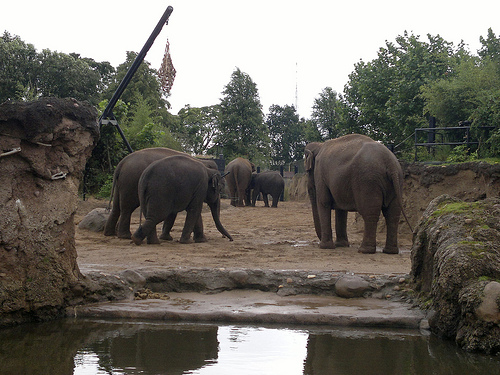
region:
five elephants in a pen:
[99, 122, 421, 263]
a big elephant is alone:
[294, 124, 419, 261]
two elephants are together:
[97, 133, 236, 252]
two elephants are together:
[218, 150, 290, 216]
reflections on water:
[14, 327, 443, 374]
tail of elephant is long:
[381, 156, 421, 233]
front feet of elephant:
[315, 207, 355, 249]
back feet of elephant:
[356, 210, 403, 259]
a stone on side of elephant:
[74, 202, 116, 240]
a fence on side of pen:
[405, 123, 474, 163]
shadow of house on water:
[71, 318, 253, 370]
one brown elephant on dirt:
[291, 124, 414, 266]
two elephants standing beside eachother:
[230, 154, 302, 221]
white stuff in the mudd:
[34, 163, 79, 190]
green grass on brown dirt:
[430, 188, 492, 248]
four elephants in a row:
[109, 135, 290, 243]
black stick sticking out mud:
[105, 0, 177, 120]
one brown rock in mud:
[319, 270, 405, 303]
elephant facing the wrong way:
[303, 114, 413, 254]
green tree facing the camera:
[215, 56, 275, 151]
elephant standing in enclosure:
[291, 137, 409, 249]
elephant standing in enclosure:
[142, 165, 242, 258]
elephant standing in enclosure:
[225, 158, 259, 205]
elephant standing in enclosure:
[258, 170, 291, 204]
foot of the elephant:
[356, 223, 382, 255]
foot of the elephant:
[384, 228, 397, 262]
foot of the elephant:
[314, 228, 337, 248]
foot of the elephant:
[338, 225, 348, 249]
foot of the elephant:
[179, 219, 195, 243]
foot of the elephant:
[195, 230, 215, 246]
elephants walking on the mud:
[105, 132, 407, 252]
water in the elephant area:
[15, 314, 463, 371]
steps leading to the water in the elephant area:
[104, 264, 426, 324]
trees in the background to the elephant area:
[354, 33, 499, 130]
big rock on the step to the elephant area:
[338, 275, 370, 297]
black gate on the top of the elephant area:
[412, 125, 492, 158]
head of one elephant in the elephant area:
[302, 142, 322, 167]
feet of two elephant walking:
[106, 211, 206, 243]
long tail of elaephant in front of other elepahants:
[230, 168, 242, 193]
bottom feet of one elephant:
[319, 238, 399, 252]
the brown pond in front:
[183, 329, 217, 360]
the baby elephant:
[159, 170, 218, 205]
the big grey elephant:
[303, 143, 411, 230]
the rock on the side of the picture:
[431, 192, 467, 241]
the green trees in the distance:
[232, 70, 260, 120]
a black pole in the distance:
[136, 15, 166, 40]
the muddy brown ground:
[260, 241, 276, 259]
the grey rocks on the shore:
[333, 265, 363, 296]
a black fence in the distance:
[415, 116, 455, 152]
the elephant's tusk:
[207, 199, 242, 243]